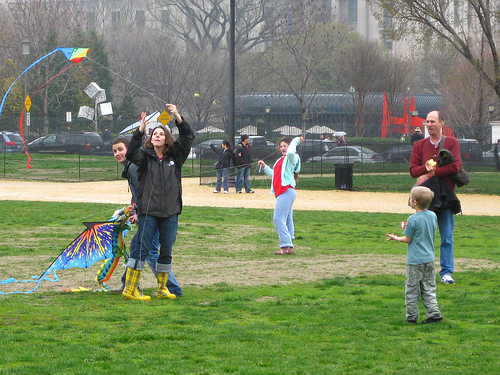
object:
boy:
[385, 185, 443, 323]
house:
[228, 90, 449, 132]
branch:
[382, 0, 474, 62]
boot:
[119, 266, 151, 300]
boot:
[156, 271, 176, 299]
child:
[386, 185, 448, 322]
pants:
[402, 257, 437, 317]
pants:
[436, 211, 455, 274]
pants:
[272, 186, 295, 248]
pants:
[128, 213, 177, 274]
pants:
[236, 165, 251, 193]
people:
[236, 131, 253, 191]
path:
[0, 176, 494, 210]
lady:
[122, 103, 195, 299]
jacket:
[125, 117, 194, 216]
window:
[347, 2, 358, 25]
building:
[218, 0, 489, 141]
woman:
[257, 134, 304, 253]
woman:
[209, 139, 232, 193]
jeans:
[437, 203, 456, 276]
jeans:
[127, 208, 179, 270]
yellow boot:
[155, 272, 176, 299]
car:
[306, 141, 384, 161]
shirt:
[402, 209, 437, 265]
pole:
[226, 2, 236, 191]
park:
[2, 151, 498, 373]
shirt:
[409, 134, 460, 193]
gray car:
[308, 146, 379, 163]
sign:
[65, 111, 71, 122]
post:
[0, 140, 117, 181]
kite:
[47, 39, 86, 63]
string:
[85, 60, 166, 104]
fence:
[357, 144, 400, 193]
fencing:
[4, 141, 109, 178]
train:
[215, 86, 498, 138]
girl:
[255, 130, 310, 256]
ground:
[301, 194, 382, 262]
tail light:
[85, 143, 90, 148]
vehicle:
[22, 131, 105, 154]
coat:
[420, 147, 470, 215]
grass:
[2, 203, 500, 371]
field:
[169, 251, 385, 367]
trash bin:
[333, 161, 353, 191]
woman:
[119, 89, 187, 308]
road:
[37, 131, 497, 164]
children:
[255, 139, 306, 257]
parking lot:
[205, 124, 430, 171]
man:
[406, 101, 460, 289]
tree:
[375, 1, 500, 146]